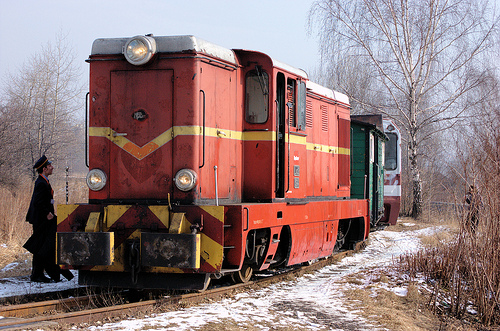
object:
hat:
[30, 155, 55, 171]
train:
[55, 33, 401, 293]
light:
[119, 35, 157, 66]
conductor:
[20, 154, 76, 282]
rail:
[1, 250, 369, 328]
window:
[242, 64, 270, 125]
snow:
[0, 218, 455, 331]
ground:
[0, 164, 499, 331]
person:
[460, 180, 483, 236]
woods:
[0, 0, 499, 331]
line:
[84, 123, 350, 161]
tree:
[304, 1, 498, 220]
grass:
[0, 197, 490, 331]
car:
[54, 33, 368, 293]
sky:
[1, 0, 499, 89]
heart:
[119, 142, 163, 182]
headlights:
[173, 169, 199, 191]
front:
[55, 35, 240, 292]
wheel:
[225, 243, 253, 286]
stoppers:
[140, 233, 196, 269]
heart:
[118, 142, 164, 186]